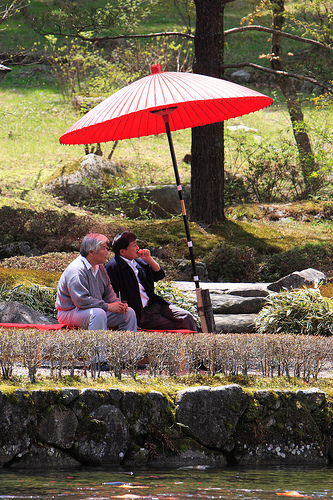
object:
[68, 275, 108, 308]
arm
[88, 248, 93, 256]
ear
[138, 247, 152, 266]
hand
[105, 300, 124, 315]
hand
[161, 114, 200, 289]
stick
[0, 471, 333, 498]
water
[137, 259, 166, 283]
arm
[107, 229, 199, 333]
man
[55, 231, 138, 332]
man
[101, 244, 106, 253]
eye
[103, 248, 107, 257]
person's nose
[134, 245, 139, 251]
person's nose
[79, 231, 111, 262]
head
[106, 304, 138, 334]
leg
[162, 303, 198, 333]
leg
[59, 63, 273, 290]
umbrella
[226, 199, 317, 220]
water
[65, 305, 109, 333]
leg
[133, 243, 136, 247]
eye